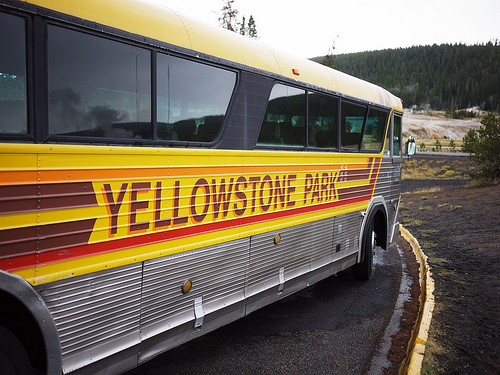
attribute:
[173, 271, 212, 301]
reflector light — yellow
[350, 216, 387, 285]
wheel — right front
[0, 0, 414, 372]
bus — Vintage tourist  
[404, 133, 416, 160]
rearview mirror — driver's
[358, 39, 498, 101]
bushes — green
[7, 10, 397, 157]
windows — tinted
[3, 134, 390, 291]
stripe — Wide yellow 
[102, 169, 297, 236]
word — YELLOWSTONE PARK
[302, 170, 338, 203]
word — YELLOWSTONE PARK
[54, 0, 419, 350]
bus — yellow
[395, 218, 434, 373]
border — yellow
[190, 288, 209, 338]
latch — silver, metal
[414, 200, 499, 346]
dirt — brown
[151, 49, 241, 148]
window — tinted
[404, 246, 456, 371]
curb — yellow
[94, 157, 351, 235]
park. — Yellowstone National   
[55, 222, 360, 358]
siding — silver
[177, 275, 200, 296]
reflector — orange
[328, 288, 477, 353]
road — paved